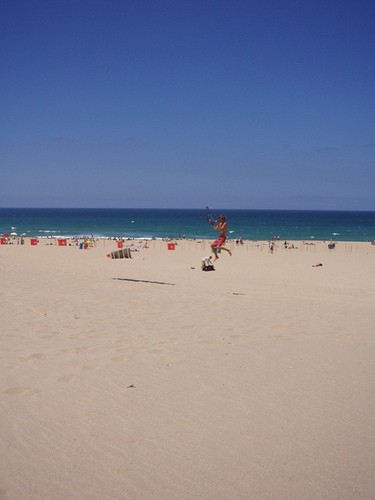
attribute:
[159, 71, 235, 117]
sky — blue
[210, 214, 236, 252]
boy — floating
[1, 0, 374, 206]
sky — blue, bright, cloudless, daytime 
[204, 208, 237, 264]
person — playing, happy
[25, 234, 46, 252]
chair — beach, summer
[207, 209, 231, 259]
man — jumping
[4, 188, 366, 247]
ocean — blue, nice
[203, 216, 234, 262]
shorts — red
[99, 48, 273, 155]
sky — blue 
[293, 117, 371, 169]
white clouds — blue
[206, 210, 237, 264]
man — jumping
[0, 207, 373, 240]
water — ocean, blue, nice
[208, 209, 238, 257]
guy — young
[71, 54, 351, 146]
sky — blue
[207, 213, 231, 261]
man — holding, in the air, shirtless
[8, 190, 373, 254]
water — ocean, nice, blue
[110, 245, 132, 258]
chair — ocean , Summer 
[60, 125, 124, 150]
clouds — white 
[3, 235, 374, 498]
sand — beach, surface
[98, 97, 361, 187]
clouds — blue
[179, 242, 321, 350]
sand — surface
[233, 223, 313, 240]
wave — crested, white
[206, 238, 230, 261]
shorts — red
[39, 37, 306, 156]
clouds — white 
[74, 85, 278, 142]
clouds — white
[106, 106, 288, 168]
clouds — white 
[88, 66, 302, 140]
sky — blue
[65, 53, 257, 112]
clouds — white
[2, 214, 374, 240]
ocean — blue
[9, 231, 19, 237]
umbrella — white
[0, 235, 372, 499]
beach — sandy, beige, summer, light colored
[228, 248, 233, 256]
foot — bare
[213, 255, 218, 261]
foot — bare